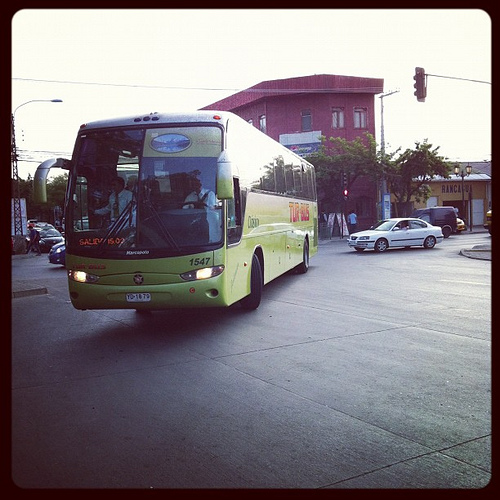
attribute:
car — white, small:
[348, 215, 446, 254]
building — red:
[202, 74, 385, 228]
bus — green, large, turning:
[63, 111, 317, 317]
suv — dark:
[406, 205, 462, 236]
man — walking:
[345, 209, 362, 234]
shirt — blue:
[346, 213, 360, 225]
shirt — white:
[185, 191, 222, 214]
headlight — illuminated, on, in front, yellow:
[182, 265, 227, 284]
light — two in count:
[453, 162, 476, 182]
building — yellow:
[397, 172, 491, 239]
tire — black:
[243, 251, 268, 313]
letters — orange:
[284, 195, 314, 225]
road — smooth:
[15, 255, 495, 496]